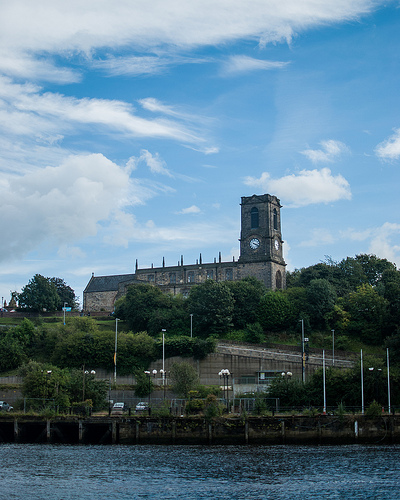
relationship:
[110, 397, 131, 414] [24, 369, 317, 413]
car parked in lot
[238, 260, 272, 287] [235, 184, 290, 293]
walls of building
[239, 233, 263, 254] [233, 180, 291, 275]
clock on building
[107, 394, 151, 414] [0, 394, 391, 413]
cars in lot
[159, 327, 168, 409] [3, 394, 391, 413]
post in lot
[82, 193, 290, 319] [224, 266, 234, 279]
building with window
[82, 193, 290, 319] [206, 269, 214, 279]
building with window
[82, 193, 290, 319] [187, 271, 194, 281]
building with window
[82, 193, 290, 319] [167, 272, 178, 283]
building with window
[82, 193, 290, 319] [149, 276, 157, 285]
building with window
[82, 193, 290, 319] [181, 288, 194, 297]
building with window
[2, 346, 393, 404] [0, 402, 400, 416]
wall next to area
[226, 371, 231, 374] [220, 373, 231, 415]
globe atop post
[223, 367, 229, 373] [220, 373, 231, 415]
globe atop post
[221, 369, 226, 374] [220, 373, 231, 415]
globe atop post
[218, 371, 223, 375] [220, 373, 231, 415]
globe atop post